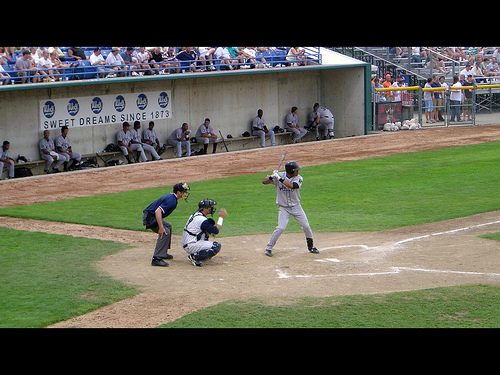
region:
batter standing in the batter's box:
[258, 146, 330, 263]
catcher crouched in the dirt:
[181, 198, 230, 268]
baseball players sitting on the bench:
[1, 101, 290, 178]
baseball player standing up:
[308, 103, 340, 138]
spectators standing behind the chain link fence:
[418, 70, 470, 120]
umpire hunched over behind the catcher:
[137, 171, 219, 273]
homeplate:
[310, 253, 343, 265]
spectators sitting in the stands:
[1, 48, 321, 80]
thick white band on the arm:
[216, 211, 226, 228]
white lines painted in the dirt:
[278, 265, 388, 284]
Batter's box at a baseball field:
[261, 237, 413, 290]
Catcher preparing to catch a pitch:
[181, 198, 231, 263]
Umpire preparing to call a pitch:
[128, 168, 202, 268]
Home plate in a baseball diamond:
[306, 246, 349, 274]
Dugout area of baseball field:
[3, 76, 380, 150]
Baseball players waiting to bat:
[116, 116, 218, 156]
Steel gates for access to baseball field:
[411, 83, 483, 134]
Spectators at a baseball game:
[8, 49, 146, 78]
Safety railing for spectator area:
[134, 60, 269, 71]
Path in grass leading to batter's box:
[1, 197, 135, 262]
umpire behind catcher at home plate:
[145, 173, 190, 267]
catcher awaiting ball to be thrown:
[178, 197, 228, 266]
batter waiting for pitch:
[262, 147, 324, 257]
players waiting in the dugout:
[0, 98, 329, 163]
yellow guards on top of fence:
[375, 77, 498, 93]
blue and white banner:
[37, 98, 192, 129]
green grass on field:
[325, 173, 497, 200]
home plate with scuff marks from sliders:
[248, 245, 429, 290]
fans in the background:
[5, 45, 499, 100]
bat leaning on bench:
[218, 125, 232, 155]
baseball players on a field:
[115, 155, 347, 283]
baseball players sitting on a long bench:
[0, 102, 370, 163]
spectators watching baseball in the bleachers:
[6, 45, 316, 75]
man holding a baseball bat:
[260, 137, 325, 262]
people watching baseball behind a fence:
[365, 67, 485, 118]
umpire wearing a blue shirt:
[141, 167, 187, 267]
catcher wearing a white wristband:
[210, 212, 226, 224]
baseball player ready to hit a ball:
[255, 140, 335, 267]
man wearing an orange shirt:
[383, 72, 393, 102]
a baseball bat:
[216, 125, 234, 157]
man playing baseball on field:
[28, 50, 448, 317]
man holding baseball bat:
[232, 128, 337, 299]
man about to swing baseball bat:
[237, 137, 308, 282]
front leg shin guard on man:
[297, 227, 328, 267]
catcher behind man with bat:
[184, 174, 274, 271]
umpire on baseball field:
[107, 171, 191, 289]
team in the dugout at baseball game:
[0, 101, 375, 172]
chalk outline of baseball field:
[265, 221, 480, 305]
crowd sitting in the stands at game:
[0, 45, 344, 126]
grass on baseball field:
[184, 148, 461, 259]